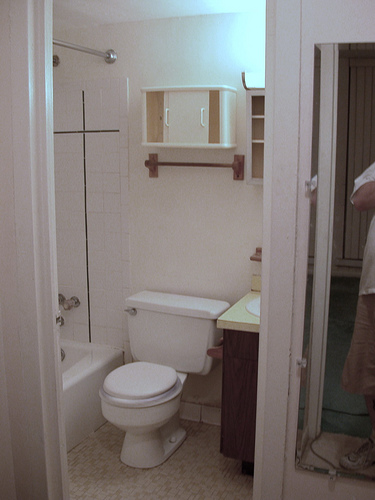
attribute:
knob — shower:
[62, 296, 79, 311]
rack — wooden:
[143, 152, 245, 182]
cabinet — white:
[140, 89, 233, 147]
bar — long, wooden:
[136, 151, 246, 183]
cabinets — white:
[139, 85, 239, 149]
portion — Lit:
[240, 65, 270, 97]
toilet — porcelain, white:
[78, 267, 252, 463]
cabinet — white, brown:
[137, 83, 238, 149]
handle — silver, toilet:
[136, 151, 269, 184]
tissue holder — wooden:
[205, 334, 223, 358]